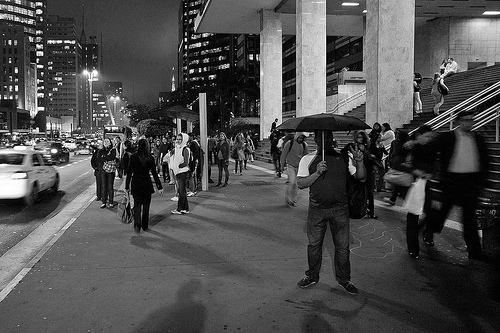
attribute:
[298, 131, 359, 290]
man — white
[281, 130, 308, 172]
hoodie — grey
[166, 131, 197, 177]
hoodie — grey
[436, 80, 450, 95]
bag — large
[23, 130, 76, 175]
vehicle — dark colored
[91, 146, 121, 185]
bag — checkered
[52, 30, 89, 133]
building — tall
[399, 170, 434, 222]
grocery bag — plastic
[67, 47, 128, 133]
light — lit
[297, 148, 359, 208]
t-shirt — white, black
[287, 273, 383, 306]
shoe — black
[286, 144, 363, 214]
shirt — black